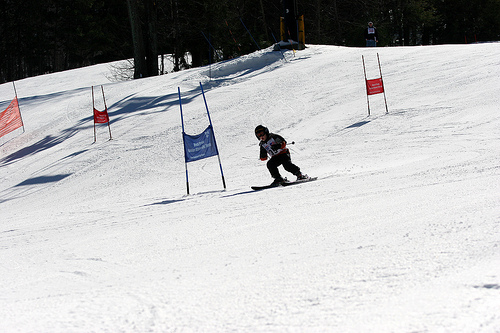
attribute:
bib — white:
[255, 140, 287, 163]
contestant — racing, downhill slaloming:
[246, 119, 320, 185]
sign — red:
[84, 79, 116, 144]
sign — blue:
[182, 126, 216, 161]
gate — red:
[83, 95, 130, 135]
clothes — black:
[256, 133, 301, 180]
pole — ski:
[276, 134, 310, 150]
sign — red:
[349, 48, 398, 105]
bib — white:
[366, 22, 378, 34]